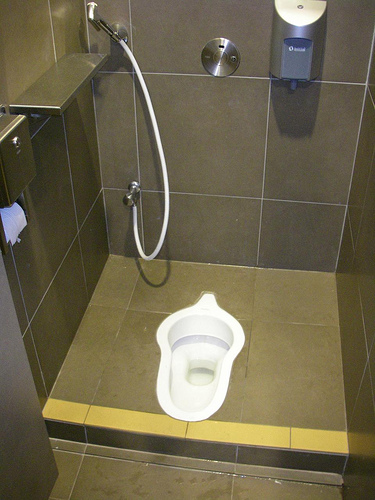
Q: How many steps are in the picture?
A: One.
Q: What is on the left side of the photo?
A: A ledge.